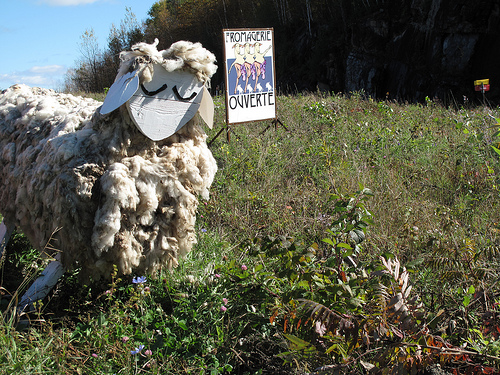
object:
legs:
[20, 254, 68, 312]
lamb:
[0, 36, 218, 306]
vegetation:
[0, 93, 499, 373]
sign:
[223, 30, 276, 124]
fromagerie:
[226, 30, 272, 42]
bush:
[301, 88, 499, 190]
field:
[9, 86, 493, 366]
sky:
[0, 0, 159, 93]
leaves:
[256, 242, 498, 374]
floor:
[1, 95, 498, 370]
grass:
[395, 143, 469, 214]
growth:
[1, 190, 498, 374]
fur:
[22, 149, 146, 218]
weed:
[302, 100, 327, 126]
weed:
[302, 130, 330, 177]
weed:
[377, 101, 394, 124]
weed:
[364, 138, 381, 166]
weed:
[388, 119, 426, 156]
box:
[125, 61, 204, 142]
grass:
[0, 277, 421, 375]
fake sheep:
[0, 37, 219, 313]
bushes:
[140, 181, 500, 370]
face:
[125, 65, 204, 142]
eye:
[172, 85, 197, 102]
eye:
[136, 81, 168, 96]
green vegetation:
[214, 187, 497, 375]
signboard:
[220, 27, 276, 125]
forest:
[275, 0, 499, 106]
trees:
[67, 1, 498, 107]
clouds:
[1, 0, 157, 93]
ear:
[100, 70, 140, 115]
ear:
[197, 86, 215, 130]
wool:
[1, 40, 218, 284]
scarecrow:
[0, 38, 217, 304]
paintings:
[138, 84, 197, 102]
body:
[0, 38, 219, 301]